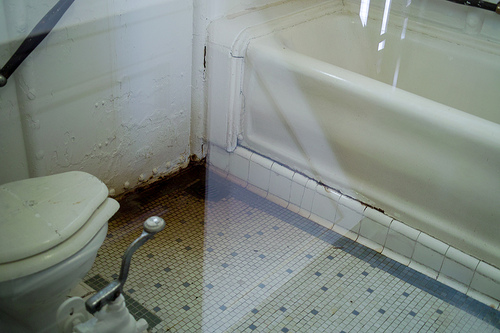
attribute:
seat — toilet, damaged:
[2, 169, 121, 314]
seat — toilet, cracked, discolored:
[6, 163, 122, 308]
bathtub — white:
[203, 4, 495, 314]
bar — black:
[2, 4, 78, 83]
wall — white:
[4, 6, 204, 197]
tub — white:
[200, 3, 485, 268]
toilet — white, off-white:
[1, 166, 124, 331]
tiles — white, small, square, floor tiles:
[66, 181, 480, 331]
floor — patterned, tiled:
[65, 166, 479, 327]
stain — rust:
[114, 164, 302, 277]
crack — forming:
[233, 136, 392, 218]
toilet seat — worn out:
[0, 166, 125, 289]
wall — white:
[4, 0, 198, 218]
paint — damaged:
[2, 2, 202, 210]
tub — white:
[213, 11, 484, 256]